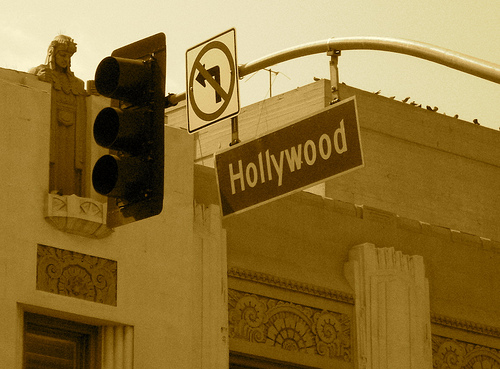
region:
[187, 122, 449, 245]
street sign that says hollywood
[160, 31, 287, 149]
no left turn sign on traffic light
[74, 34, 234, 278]
traffic light in photo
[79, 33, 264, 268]
black traffic light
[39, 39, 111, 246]
statue in photo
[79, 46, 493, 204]
traffic light on a pole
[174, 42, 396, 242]
two street signs on traffic light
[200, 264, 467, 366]
details on building in photo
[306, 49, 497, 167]
birds perched on roof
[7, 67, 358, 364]
stone building in photo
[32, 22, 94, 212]
a stone statue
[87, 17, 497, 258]
a traffic light signal and pole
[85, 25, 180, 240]
a black traffic light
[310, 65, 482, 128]
several birds sitting on roof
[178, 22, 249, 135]
a sign with an arrow and circle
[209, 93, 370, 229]
a sign with the letters Hollywood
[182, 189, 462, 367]
two carved pillars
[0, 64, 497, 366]
a stone building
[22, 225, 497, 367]
three ornately carved mosaics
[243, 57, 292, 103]
an antenna on top of the roof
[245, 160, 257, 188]
a letter O written in white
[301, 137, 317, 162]
a letter O written in white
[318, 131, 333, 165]
a letter O written in white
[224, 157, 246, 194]
a letter H written in white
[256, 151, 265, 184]
a letter L written in white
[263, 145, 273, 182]
a letter L written in white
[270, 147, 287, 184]
a letter Y written in white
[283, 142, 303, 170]
a letter W written in white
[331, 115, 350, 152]
a letter D written in white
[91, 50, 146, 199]
Traffic lights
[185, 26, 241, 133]
No left turn sign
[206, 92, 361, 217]
Hollywood sign on traffic light pole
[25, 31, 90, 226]
Rain water drain with bust of lady's head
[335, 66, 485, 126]
birds on top of roof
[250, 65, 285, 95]
satellite antenna on top of roof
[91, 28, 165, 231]
black traffic light on pole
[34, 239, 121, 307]
filligree inlay on exterior wall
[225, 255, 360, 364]
large filligree inlet on exterior wall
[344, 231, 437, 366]
post-modern architecture design on support beam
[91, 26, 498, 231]
support beam holding traffic light and signs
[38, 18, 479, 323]
The picture is in black and white.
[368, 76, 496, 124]
Birds sitting on top of the building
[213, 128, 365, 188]
The sign says Hollywood.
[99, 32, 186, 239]
A street traffic light hanging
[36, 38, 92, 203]
A statue on the building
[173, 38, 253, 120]
The sign no left turn hangs by the traffic light.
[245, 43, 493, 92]
The rod has signs hanging from it.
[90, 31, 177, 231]
The traffic sign is black.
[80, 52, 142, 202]
The traffic light has 3 lights.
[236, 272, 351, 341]
A pattern is displayed on the edge of the building.